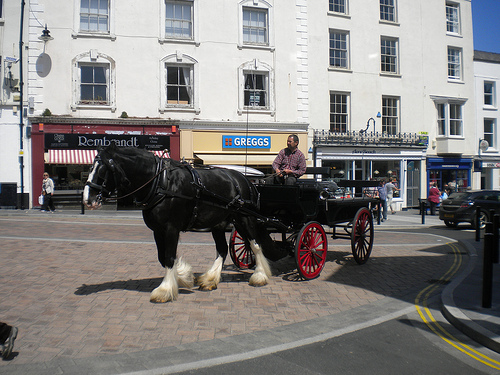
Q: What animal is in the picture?
A: Horse.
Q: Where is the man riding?
A: Carriage.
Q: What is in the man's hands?
A: Horse reins.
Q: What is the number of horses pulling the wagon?
A: 1.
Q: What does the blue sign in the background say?
A: GREGGS.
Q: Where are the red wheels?
A: On the wagon.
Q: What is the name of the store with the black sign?
A: Rembrandt.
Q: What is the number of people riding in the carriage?
A: 1.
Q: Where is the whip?
A: Side of carriage.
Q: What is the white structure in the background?
A: Building.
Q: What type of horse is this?
A: A Clydesdale.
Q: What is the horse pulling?
A: A carriage.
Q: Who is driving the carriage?
A: A man in a long sleeve shirt.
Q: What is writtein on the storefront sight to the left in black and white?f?
A: Rembrandt.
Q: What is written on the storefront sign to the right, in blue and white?
A: Greggs.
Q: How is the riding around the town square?
A: Horse and buggy.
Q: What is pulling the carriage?
A: A black horse.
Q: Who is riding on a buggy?
A: A man in a purple shirt.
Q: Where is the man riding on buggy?
A: The town square.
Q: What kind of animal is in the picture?
A: Horse.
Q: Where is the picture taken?
A: City street.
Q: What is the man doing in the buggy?
A: Driving the horse.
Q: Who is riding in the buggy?
A: A man.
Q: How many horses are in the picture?
A: One.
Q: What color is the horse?
A: Black and white.